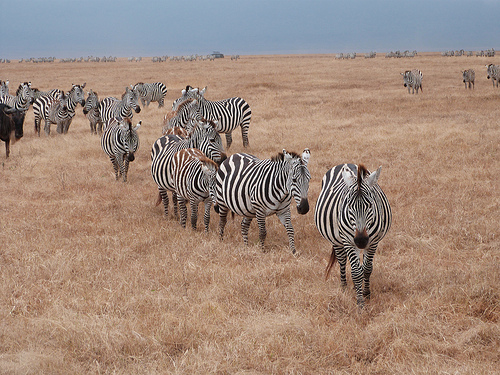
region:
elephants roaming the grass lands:
[347, 48, 499, 56]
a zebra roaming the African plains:
[315, 162, 391, 307]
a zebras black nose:
[296, 198, 309, 214]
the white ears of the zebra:
[366, 165, 382, 183]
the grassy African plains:
[1, 0, 499, 374]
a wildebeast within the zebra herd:
[1, 103, 26, 158]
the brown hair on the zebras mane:
[266, 150, 301, 162]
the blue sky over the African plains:
[0, 0, 499, 59]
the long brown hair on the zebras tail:
[324, 243, 337, 283]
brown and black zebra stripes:
[172, 146, 217, 201]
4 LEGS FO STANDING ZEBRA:
[211, 213, 303, 254]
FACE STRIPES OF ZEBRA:
[347, 196, 369, 221]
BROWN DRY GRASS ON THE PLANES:
[426, 143, 489, 208]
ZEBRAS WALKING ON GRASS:
[392, 65, 497, 116]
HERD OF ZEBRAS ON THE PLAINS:
[1, 50, 496, 63]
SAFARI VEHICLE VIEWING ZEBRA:
[203, 45, 229, 60]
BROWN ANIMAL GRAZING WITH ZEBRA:
[0, 98, 25, 163]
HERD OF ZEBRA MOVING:
[27, 80, 402, 308]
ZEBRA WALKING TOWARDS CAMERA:
[315, 160, 392, 314]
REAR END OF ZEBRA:
[216, 152, 260, 208]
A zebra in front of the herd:
[313, 152, 384, 301]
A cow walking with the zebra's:
[0, 103, 34, 158]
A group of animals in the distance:
[8, 44, 206, 61]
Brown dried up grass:
[64, 249, 348, 361]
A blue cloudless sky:
[100, 2, 362, 52]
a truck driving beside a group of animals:
[206, 47, 229, 59]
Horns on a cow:
[4, 102, 29, 117]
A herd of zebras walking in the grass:
[7, 63, 385, 316]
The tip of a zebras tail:
[318, 246, 341, 279]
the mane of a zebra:
[264, 143, 302, 163]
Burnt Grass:
[266, 75, 402, 161]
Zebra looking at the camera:
[326, 160, 401, 319]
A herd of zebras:
[11, 63, 484, 335]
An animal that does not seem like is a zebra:
[1, 108, 8, 153]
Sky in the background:
[74, 10, 239, 42]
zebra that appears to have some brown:
[164, 143, 219, 232]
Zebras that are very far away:
[330, 36, 497, 61]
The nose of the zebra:
[354, 231, 374, 248]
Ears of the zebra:
[342, 168, 406, 191]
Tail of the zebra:
[318, 246, 339, 285]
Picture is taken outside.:
[32, 28, 379, 370]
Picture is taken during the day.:
[54, 29, 474, 71]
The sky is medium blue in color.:
[57, 14, 466, 42]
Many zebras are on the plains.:
[35, 50, 422, 320]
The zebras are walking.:
[35, 76, 435, 290]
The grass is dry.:
[49, 210, 359, 363]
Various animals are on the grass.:
[7, 76, 69, 165]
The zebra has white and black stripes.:
[329, 142, 424, 352]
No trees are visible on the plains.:
[44, 35, 479, 105]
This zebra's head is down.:
[157, 145, 234, 225]